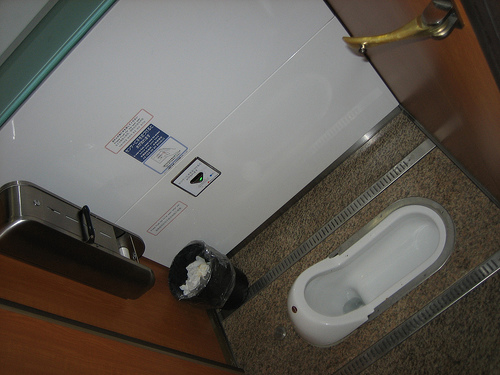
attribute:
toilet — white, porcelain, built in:
[276, 201, 457, 350]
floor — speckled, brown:
[183, 122, 498, 373]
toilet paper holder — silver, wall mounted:
[2, 181, 159, 301]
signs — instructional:
[103, 116, 223, 234]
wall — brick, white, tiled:
[2, 3, 376, 257]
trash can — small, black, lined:
[157, 239, 250, 311]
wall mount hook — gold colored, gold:
[333, 3, 459, 51]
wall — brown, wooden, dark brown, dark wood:
[0, 212, 243, 374]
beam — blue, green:
[4, 5, 112, 127]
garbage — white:
[174, 254, 211, 295]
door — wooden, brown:
[338, 4, 499, 198]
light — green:
[198, 174, 205, 185]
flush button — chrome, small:
[271, 320, 286, 344]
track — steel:
[327, 266, 499, 375]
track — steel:
[227, 137, 433, 315]